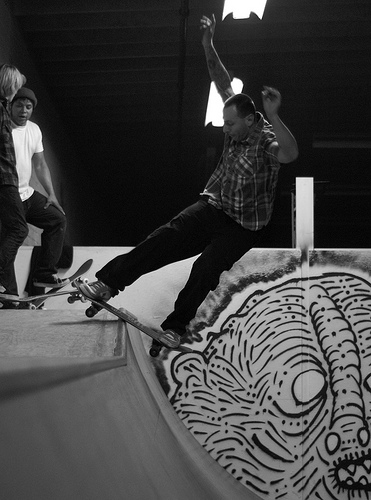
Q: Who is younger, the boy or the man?
A: The boy is younger than the man.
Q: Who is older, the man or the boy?
A: The man is older than the boy.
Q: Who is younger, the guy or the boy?
A: The boy is younger than the guy.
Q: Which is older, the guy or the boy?
A: The guy is older than the boy.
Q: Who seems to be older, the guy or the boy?
A: The guy is older than the boy.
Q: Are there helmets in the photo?
A: No, there are no helmets.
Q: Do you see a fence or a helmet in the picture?
A: No, there are no helmets or fences.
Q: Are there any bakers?
A: No, there are no bakers.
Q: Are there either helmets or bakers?
A: No, there are no bakers or helmets.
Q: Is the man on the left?
A: Yes, the man is on the left of the image.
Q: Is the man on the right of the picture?
A: No, the man is on the left of the image.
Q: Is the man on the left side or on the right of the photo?
A: The man is on the left of the image.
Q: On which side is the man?
A: The man is on the left of the image.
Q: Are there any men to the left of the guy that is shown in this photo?
A: Yes, there is a man to the left of the guy.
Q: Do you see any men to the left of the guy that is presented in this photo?
A: Yes, there is a man to the left of the guy.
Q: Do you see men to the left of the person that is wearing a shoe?
A: Yes, there is a man to the left of the guy.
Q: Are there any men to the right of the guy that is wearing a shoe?
A: No, the man is to the left of the guy.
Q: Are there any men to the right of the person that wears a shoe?
A: No, the man is to the left of the guy.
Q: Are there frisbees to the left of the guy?
A: No, there is a man to the left of the guy.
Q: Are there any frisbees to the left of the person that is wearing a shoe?
A: No, there is a man to the left of the guy.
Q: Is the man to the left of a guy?
A: Yes, the man is to the left of a guy.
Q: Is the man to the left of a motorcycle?
A: No, the man is to the left of a guy.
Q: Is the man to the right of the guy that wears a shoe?
A: No, the man is to the left of the guy.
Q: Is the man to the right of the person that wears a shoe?
A: No, the man is to the left of the guy.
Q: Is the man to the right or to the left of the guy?
A: The man is to the left of the guy.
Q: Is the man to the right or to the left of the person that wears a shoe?
A: The man is to the left of the guy.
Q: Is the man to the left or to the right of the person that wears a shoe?
A: The man is to the left of the guy.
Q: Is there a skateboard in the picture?
A: Yes, there is a skateboard.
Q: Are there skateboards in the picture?
A: Yes, there is a skateboard.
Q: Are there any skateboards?
A: Yes, there is a skateboard.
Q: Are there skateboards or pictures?
A: Yes, there is a skateboard.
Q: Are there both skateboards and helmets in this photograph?
A: No, there is a skateboard but no helmets.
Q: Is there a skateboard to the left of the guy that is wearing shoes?
A: Yes, there is a skateboard to the left of the guy.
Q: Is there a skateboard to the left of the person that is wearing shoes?
A: Yes, there is a skateboard to the left of the guy.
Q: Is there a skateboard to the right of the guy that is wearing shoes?
A: No, the skateboard is to the left of the guy.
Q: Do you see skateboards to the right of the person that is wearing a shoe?
A: No, the skateboard is to the left of the guy.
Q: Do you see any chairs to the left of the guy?
A: No, there is a skateboard to the left of the guy.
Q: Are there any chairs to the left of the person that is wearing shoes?
A: No, there is a skateboard to the left of the guy.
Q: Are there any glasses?
A: No, there are no glasses.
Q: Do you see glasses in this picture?
A: No, there are no glasses.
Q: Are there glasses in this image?
A: No, there are no glasses.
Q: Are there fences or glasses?
A: No, there are no glasses or fences.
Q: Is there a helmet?
A: No, there are no helmets.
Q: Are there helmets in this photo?
A: No, there are no helmets.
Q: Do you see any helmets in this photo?
A: No, there are no helmets.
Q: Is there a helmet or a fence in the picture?
A: No, there are no helmets or fences.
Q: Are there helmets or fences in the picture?
A: No, there are no helmets or fences.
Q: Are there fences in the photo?
A: No, there are no fences.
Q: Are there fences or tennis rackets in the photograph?
A: No, there are no fences or tennis rackets.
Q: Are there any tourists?
A: No, there are no tourists.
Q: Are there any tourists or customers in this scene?
A: No, there are no tourists or customers.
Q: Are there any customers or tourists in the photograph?
A: No, there are no tourists or customers.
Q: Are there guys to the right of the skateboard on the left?
A: Yes, there is a guy to the right of the skateboard.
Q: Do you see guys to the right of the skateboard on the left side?
A: Yes, there is a guy to the right of the skateboard.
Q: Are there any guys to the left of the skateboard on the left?
A: No, the guy is to the right of the skateboard.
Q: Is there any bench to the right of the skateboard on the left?
A: No, there is a guy to the right of the skateboard.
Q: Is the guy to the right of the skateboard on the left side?
A: Yes, the guy is to the right of the skateboard.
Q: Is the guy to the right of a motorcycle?
A: No, the guy is to the right of the skateboard.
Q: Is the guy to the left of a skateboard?
A: No, the guy is to the right of a skateboard.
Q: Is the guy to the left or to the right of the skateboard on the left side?
A: The guy is to the right of the skateboard.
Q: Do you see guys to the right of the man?
A: Yes, there is a guy to the right of the man.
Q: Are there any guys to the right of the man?
A: Yes, there is a guy to the right of the man.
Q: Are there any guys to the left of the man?
A: No, the guy is to the right of the man.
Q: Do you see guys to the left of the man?
A: No, the guy is to the right of the man.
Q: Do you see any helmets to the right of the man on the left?
A: No, there is a guy to the right of the man.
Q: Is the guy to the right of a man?
A: Yes, the guy is to the right of a man.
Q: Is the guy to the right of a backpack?
A: No, the guy is to the right of a man.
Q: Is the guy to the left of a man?
A: No, the guy is to the right of a man.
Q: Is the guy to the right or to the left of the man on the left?
A: The guy is to the right of the man.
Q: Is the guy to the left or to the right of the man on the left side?
A: The guy is to the right of the man.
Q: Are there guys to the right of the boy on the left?
A: Yes, there is a guy to the right of the boy.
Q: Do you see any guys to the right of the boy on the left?
A: Yes, there is a guy to the right of the boy.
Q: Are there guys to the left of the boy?
A: No, the guy is to the right of the boy.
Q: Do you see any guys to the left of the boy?
A: No, the guy is to the right of the boy.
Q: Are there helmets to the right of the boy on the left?
A: No, there is a guy to the right of the boy.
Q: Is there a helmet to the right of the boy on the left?
A: No, there is a guy to the right of the boy.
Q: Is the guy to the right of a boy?
A: Yes, the guy is to the right of a boy.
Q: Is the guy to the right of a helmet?
A: No, the guy is to the right of a boy.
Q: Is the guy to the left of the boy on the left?
A: No, the guy is to the right of the boy.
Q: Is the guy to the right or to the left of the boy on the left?
A: The guy is to the right of the boy.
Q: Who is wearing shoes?
A: The guy is wearing shoes.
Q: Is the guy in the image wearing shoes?
A: Yes, the guy is wearing shoes.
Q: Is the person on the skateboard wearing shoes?
A: Yes, the guy is wearing shoes.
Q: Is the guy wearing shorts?
A: No, the guy is wearing shoes.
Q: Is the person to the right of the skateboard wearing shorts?
A: No, the guy is wearing shoes.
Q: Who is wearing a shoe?
A: The guy is wearing a shoe.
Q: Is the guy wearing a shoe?
A: Yes, the guy is wearing a shoe.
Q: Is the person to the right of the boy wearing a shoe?
A: Yes, the guy is wearing a shoe.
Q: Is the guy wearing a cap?
A: No, the guy is wearing a shoe.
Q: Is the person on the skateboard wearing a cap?
A: No, the guy is wearing a shoe.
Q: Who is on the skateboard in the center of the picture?
A: The guy is on the skateboard.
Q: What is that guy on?
A: The guy is on the skateboard.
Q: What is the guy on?
A: The guy is on the skateboard.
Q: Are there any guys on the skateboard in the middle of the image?
A: Yes, there is a guy on the skateboard.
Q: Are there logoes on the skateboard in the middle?
A: No, there is a guy on the skateboard.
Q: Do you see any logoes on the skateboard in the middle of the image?
A: No, there is a guy on the skateboard.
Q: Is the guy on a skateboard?
A: Yes, the guy is on a skateboard.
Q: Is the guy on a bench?
A: No, the guy is on a skateboard.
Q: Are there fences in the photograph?
A: No, there are no fences.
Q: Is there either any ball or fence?
A: No, there are no fences or balls.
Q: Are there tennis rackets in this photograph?
A: No, there are no tennis rackets.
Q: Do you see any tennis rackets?
A: No, there are no tennis rackets.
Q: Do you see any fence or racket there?
A: No, there are no rackets or fences.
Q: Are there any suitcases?
A: No, there are no suitcases.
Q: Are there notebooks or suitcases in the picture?
A: No, there are no suitcases or notebooks.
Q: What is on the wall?
A: The graffiti is on the wall.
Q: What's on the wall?
A: The graffiti is on the wall.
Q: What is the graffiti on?
A: The graffiti is on the wall.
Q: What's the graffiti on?
A: The graffiti is on the wall.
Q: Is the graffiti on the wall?
A: Yes, the graffiti is on the wall.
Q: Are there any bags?
A: No, there are no bags.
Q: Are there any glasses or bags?
A: No, there are no bags or glasses.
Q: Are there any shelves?
A: No, there are no shelves.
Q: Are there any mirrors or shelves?
A: No, there are no shelves or mirrors.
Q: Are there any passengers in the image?
A: No, there are no passengers.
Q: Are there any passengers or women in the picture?
A: No, there are no passengers or women.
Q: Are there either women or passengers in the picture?
A: No, there are no passengers or women.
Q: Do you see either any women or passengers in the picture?
A: No, there are no passengers or women.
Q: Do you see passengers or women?
A: No, there are no passengers or women.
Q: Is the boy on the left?
A: Yes, the boy is on the left of the image.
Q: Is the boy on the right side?
A: No, the boy is on the left of the image.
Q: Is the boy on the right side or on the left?
A: The boy is on the left of the image.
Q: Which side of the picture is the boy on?
A: The boy is on the left of the image.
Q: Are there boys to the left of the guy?
A: Yes, there is a boy to the left of the guy.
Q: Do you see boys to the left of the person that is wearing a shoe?
A: Yes, there is a boy to the left of the guy.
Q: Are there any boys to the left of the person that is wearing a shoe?
A: Yes, there is a boy to the left of the guy.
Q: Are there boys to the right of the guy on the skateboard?
A: No, the boy is to the left of the guy.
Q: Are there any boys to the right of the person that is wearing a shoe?
A: No, the boy is to the left of the guy.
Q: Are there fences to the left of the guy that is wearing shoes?
A: No, there is a boy to the left of the guy.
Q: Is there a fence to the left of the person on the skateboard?
A: No, there is a boy to the left of the guy.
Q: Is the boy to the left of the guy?
A: Yes, the boy is to the left of the guy.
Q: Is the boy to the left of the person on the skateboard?
A: Yes, the boy is to the left of the guy.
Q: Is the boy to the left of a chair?
A: No, the boy is to the left of the guy.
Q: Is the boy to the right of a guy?
A: No, the boy is to the left of a guy.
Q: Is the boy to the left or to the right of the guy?
A: The boy is to the left of the guy.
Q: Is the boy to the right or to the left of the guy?
A: The boy is to the left of the guy.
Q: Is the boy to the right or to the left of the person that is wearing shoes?
A: The boy is to the left of the guy.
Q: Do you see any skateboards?
A: Yes, there is a skateboard.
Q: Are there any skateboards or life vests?
A: Yes, there is a skateboard.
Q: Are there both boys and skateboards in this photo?
A: Yes, there are both a skateboard and a boy.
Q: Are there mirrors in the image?
A: No, there are no mirrors.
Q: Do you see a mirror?
A: No, there are no mirrors.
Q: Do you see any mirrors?
A: No, there are no mirrors.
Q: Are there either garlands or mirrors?
A: No, there are no mirrors or garlands.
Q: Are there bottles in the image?
A: No, there are no bottles.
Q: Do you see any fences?
A: No, there are no fences.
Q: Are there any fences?
A: No, there are no fences.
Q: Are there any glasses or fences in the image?
A: No, there are no fences or glasses.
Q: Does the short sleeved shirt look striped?
A: Yes, the shirt is striped.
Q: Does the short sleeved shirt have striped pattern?
A: Yes, the shirt is striped.